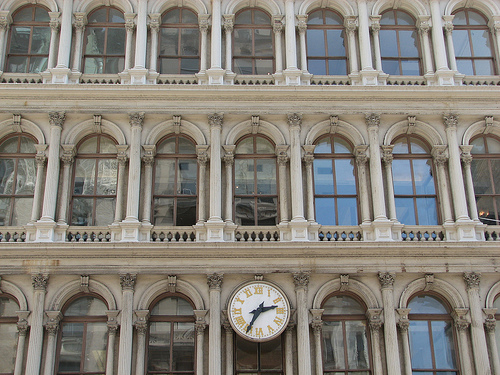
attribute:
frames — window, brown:
[126, 258, 217, 369]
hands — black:
[247, 296, 279, 332]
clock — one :
[219, 281, 297, 344]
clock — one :
[230, 280, 297, 348]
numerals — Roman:
[229, 277, 291, 336]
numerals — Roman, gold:
[227, 288, 300, 344]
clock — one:
[221, 276, 294, 349]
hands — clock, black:
[238, 298, 283, 333]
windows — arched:
[13, 105, 472, 235]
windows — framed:
[27, 112, 497, 240]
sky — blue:
[311, 148, 360, 216]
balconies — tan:
[22, 210, 496, 275]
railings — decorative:
[156, 195, 286, 248]